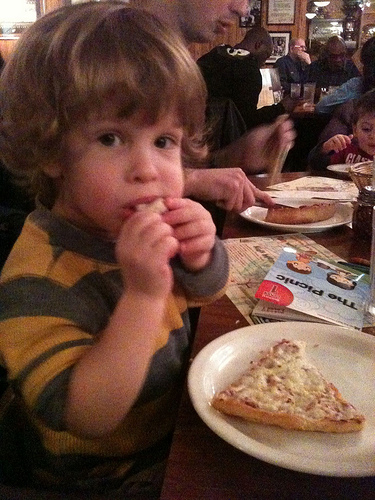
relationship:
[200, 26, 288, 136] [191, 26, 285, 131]
man weariing dark man wearing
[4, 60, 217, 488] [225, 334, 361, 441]
young kid eating food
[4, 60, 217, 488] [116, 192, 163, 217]
young kid with mouth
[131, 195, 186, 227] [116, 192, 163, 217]
food in mouth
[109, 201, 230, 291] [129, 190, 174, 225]
hands bringing food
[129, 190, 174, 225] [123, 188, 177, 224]
food to mouth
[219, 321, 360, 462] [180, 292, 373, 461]
cheese pizza on plate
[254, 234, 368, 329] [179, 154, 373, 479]
kids book on table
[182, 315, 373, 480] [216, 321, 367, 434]
plate filled with pizza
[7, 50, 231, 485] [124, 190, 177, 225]
little boy with food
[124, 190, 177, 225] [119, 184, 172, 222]
food in mouth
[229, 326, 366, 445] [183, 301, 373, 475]
pizza on white plate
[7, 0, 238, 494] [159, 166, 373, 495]
child sitting at table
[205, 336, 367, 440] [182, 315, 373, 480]
pizza on plate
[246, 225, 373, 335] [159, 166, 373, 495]
book on table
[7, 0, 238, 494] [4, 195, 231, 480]
child wearing sweater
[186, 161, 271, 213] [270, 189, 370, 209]
hand holding knife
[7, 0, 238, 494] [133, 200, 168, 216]
child biting food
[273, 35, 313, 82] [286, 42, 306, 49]
man wearing glasses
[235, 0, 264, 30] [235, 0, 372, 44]
picture on wall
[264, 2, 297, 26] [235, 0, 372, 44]
picture on wall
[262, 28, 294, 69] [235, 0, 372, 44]
picture on wall